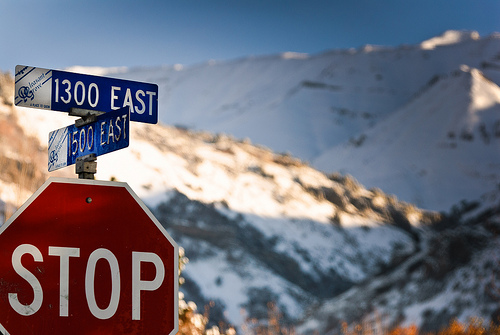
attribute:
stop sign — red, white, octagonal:
[0, 177, 180, 333]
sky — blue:
[1, 1, 499, 73]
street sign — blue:
[47, 104, 129, 172]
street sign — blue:
[15, 64, 157, 117]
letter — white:
[7, 243, 44, 317]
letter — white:
[48, 245, 82, 318]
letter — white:
[84, 246, 121, 320]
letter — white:
[131, 251, 165, 323]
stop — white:
[7, 242, 164, 319]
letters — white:
[52, 78, 157, 117]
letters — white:
[66, 112, 130, 156]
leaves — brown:
[176, 246, 500, 334]